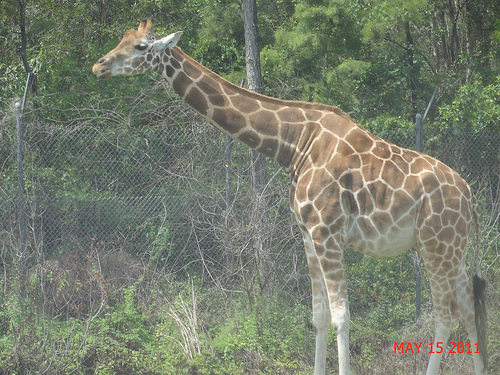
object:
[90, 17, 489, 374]
giraffe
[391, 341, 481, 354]
date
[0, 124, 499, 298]
fence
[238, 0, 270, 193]
trunk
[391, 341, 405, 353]
letters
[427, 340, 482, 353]
numbers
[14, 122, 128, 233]
metal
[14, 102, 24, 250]
post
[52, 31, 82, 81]
green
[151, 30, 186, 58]
ears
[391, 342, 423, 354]
may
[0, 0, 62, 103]
trees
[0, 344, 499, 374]
ground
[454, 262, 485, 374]
legs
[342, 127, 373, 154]
spots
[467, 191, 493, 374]
tail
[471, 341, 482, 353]
red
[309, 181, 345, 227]
pattern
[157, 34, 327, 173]
big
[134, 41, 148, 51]
eyes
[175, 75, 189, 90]
brown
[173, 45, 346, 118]
mane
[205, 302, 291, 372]
brush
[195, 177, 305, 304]
dead